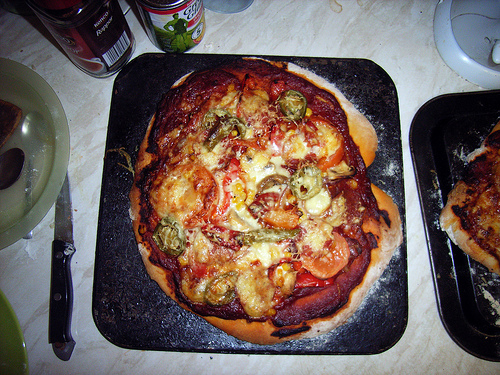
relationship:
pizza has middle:
[128, 59, 399, 340] [197, 108, 320, 279]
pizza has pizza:
[128, 59, 399, 340] [128, 59, 399, 340]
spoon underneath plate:
[20, 113, 50, 233] [1, 58, 68, 249]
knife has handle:
[49, 169, 77, 361] [46, 243, 74, 359]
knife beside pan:
[49, 169, 77, 361] [91, 47, 407, 362]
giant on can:
[164, 12, 193, 49] [135, 1, 206, 53]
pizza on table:
[128, 59, 399, 340] [2, 0, 499, 375]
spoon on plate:
[0, 148, 27, 192] [1, 58, 68, 249]